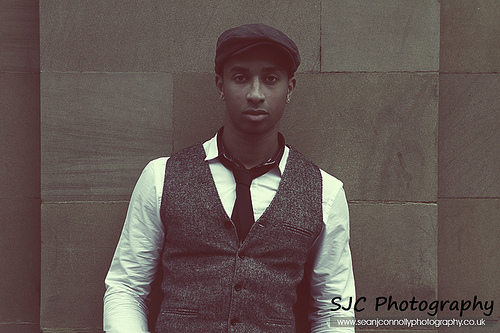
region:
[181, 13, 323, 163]
a clean shaven man.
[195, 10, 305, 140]
man wearing a hat on head.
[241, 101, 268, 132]
mouth of a person.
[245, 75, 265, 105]
nose of a person.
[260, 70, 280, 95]
left eye of a person.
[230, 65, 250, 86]
right eye of a person.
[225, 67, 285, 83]
two eyes of a person.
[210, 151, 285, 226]
person wearing a black tie.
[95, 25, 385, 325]
man wearing a gray vest.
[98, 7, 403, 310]
man posing standing next to a wall.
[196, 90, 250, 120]
The man is wearing an earring.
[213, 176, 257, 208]
The man is wearing a tie.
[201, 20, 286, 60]
The man is wearing a hat.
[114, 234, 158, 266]
The shirt is white.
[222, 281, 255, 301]
The vest has buttons.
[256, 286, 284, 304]
The vest is blue.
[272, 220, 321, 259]
The vest has pockets.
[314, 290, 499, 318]
The name of the company that took the photo.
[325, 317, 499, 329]
The website of the company.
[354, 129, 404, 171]
The wall is grey.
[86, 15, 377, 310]
young man leaning against wall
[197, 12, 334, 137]
dark cap on top of head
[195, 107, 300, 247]
black tie loosened at neck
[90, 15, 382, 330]
man wearing white dress shirt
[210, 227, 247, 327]
black buttons closed on front of vest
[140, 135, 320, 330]
tweed vest with pockets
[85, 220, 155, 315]
wrinkles on both sides of bent elbow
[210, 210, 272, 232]
top button left unbuttoned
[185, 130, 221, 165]
collar tip over vest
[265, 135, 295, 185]
collar tip under vest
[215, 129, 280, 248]
Man wearing dark tie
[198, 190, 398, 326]
Man wearing white shirt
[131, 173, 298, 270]
Man wearing gray vest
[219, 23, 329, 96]
Man wearing black cap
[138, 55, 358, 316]
Man in front of wall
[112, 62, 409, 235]
Wall behind man is gray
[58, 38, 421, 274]
Wall is concrete blocks behind man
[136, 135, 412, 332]
Man's white shirt is button down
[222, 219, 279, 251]
Top button on vest is open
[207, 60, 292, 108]
Man has dark eyes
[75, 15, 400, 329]
a man is standing against a wall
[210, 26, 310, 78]
man is wearing a paperboy hat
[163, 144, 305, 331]
man is wearing a gray vest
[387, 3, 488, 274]
a brick wall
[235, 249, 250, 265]
button of the vest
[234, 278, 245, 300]
button of the vest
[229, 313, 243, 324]
button of the vest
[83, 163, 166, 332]
white sleeve of the man's shirt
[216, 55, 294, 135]
face of the man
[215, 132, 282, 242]
man is wearing a black tie